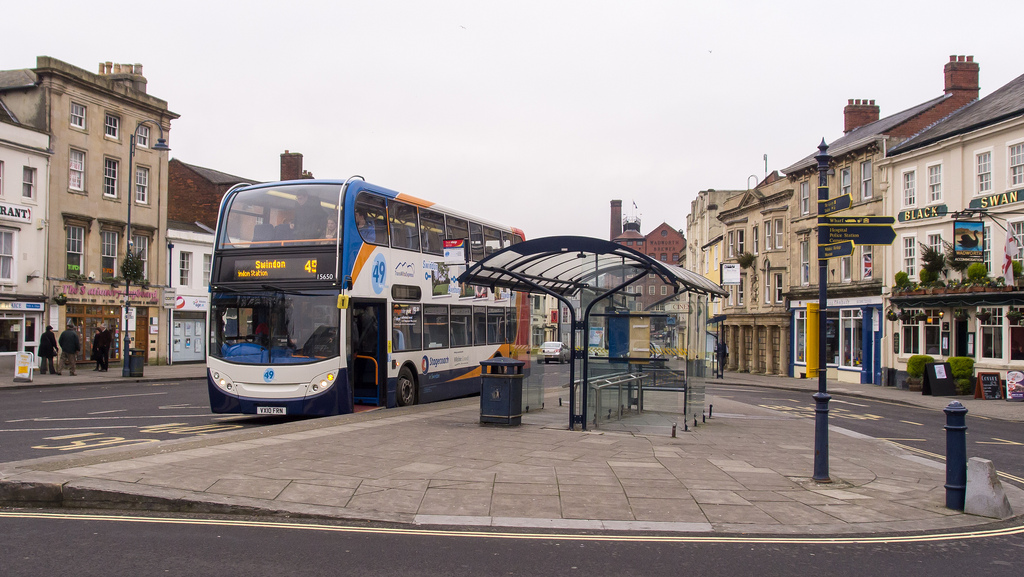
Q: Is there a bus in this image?
A: Yes, there is a bus.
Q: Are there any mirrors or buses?
A: Yes, there is a bus.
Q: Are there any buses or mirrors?
A: Yes, there is a bus.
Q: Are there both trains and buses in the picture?
A: No, there is a bus but no trains.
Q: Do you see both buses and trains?
A: No, there is a bus but no trains.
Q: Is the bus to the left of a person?
A: No, the bus is to the right of a person.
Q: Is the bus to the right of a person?
A: Yes, the bus is to the right of a person.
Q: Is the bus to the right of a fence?
A: No, the bus is to the right of a person.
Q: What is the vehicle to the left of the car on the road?
A: The vehicle is a bus.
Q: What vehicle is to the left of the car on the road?
A: The vehicle is a bus.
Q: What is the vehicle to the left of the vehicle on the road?
A: The vehicle is a bus.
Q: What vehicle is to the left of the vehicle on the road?
A: The vehicle is a bus.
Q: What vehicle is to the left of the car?
A: The vehicle is a bus.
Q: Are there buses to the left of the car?
A: Yes, there is a bus to the left of the car.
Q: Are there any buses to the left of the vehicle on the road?
A: Yes, there is a bus to the left of the car.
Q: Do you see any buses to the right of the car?
A: No, the bus is to the left of the car.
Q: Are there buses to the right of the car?
A: No, the bus is to the left of the car.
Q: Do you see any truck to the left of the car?
A: No, there is a bus to the left of the car.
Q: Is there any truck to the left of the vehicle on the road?
A: No, there is a bus to the left of the car.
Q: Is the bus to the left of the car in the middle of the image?
A: Yes, the bus is to the left of the car.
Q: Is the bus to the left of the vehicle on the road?
A: Yes, the bus is to the left of the car.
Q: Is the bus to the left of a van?
A: No, the bus is to the left of the car.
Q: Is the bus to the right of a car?
A: No, the bus is to the left of a car.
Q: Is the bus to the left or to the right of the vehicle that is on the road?
A: The bus is to the left of the car.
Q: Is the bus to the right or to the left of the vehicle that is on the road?
A: The bus is to the left of the car.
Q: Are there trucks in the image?
A: No, there are no trucks.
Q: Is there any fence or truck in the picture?
A: No, there are no trucks or fences.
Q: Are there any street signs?
A: Yes, there is a street sign.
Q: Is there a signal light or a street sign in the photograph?
A: Yes, there is a street sign.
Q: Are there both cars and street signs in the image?
A: Yes, there are both a street sign and a car.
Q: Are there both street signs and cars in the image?
A: Yes, there are both a street sign and a car.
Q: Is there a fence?
A: No, there are no fences.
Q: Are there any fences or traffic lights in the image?
A: No, there are no fences or traffic lights.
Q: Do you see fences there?
A: No, there are no fences.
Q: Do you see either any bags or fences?
A: No, there are no fences or bags.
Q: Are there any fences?
A: No, there are no fences.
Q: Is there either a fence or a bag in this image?
A: No, there are no fences or bags.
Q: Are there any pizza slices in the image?
A: No, there are no pizza slices.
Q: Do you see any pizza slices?
A: No, there are no pizza slices.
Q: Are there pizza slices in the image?
A: No, there are no pizza slices.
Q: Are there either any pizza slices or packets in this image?
A: No, there are no pizza slices or packets.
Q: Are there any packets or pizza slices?
A: No, there are no pizza slices or packets.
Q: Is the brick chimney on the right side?
A: Yes, the chimney is on the right of the image.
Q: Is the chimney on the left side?
A: No, the chimney is on the right of the image.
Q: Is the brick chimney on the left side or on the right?
A: The chimney is on the right of the image.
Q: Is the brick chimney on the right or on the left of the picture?
A: The chimney is on the right of the image.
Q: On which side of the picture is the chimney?
A: The chimney is on the right of the image.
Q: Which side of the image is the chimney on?
A: The chimney is on the right of the image.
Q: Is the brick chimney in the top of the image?
A: Yes, the chimney is in the top of the image.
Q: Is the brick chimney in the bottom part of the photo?
A: No, the chimney is in the top of the image.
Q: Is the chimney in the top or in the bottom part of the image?
A: The chimney is in the top of the image.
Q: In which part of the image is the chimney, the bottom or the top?
A: The chimney is in the top of the image.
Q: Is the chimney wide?
A: Yes, the chimney is wide.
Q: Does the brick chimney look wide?
A: Yes, the chimney is wide.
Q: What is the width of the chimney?
A: The chimney is wide.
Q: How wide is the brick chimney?
A: The chimney is wide.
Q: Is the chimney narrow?
A: No, the chimney is wide.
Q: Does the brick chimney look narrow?
A: No, the chimney is wide.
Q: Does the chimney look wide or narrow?
A: The chimney is wide.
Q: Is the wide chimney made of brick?
A: Yes, the chimney is made of brick.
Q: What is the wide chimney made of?
A: The chimney is made of brick.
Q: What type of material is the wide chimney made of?
A: The chimney is made of brick.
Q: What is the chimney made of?
A: The chimney is made of brick.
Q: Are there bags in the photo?
A: No, there are no bags.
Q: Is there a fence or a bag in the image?
A: No, there are no bags or fences.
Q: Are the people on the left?
A: Yes, the people are on the left of the image.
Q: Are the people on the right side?
A: No, the people are on the left of the image.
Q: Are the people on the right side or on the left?
A: The people are on the left of the image.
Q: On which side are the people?
A: The people are on the left of the image.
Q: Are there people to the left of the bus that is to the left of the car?
A: Yes, there are people to the left of the bus.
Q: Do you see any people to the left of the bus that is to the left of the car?
A: Yes, there are people to the left of the bus.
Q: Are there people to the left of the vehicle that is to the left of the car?
A: Yes, there are people to the left of the bus.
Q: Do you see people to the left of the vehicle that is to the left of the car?
A: Yes, there are people to the left of the bus.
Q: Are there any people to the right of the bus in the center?
A: No, the people are to the left of the bus.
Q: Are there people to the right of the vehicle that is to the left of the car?
A: No, the people are to the left of the bus.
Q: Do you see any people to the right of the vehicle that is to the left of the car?
A: No, the people are to the left of the bus.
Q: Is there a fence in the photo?
A: No, there are no fences.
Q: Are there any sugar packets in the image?
A: No, there are no sugar packets.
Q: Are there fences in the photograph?
A: No, there are no fences.